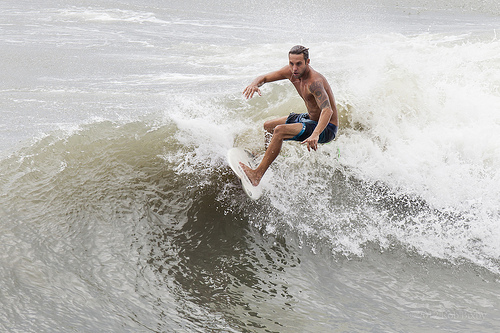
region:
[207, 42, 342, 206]
White man on surf board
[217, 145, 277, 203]
white surf board cutting wave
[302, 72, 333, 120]
tattoo on upper arm from shoulder to elbow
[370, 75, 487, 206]
froth created by rolling wave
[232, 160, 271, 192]
foot on white surf board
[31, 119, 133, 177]
top of wave about to roll over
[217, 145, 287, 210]
surf board cutting through the wave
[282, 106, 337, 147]
blue swim trunks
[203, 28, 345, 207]
man balancing on surf board on top of wave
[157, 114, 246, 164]
spray from surfboard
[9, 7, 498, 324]
Man surfing across a wave crest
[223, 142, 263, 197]
White surfboard in the water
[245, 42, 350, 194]
man with dark hair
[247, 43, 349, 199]
man in blue swimsuit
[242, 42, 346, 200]
man with tattoos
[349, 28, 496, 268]
wave crest splashing around man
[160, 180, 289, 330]
reflection cast on the grey water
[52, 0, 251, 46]
new wave forming in the distance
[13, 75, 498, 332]
waves in grey water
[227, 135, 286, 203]
bare feet on surfboard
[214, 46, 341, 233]
one man is surfing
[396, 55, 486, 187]
water is splashing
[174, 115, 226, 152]
waves are white in color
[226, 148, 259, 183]
surfing board is white in color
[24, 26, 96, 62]
water is blue in color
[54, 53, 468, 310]
daytime picture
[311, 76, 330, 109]
tattoo marks on arms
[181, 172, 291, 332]
reflection is seen in water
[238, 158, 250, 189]
letters are black in color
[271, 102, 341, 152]
trouser is black in color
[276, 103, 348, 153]
blue and black shorts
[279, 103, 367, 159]
cold, wet board shorts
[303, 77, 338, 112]
a large black arm tattoo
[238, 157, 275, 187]
a man's bare foot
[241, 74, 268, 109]
a open hand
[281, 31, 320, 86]
a man with wet hair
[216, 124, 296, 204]
a nice white surf board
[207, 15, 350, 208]
a young man surfing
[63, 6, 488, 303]
a natural ocean wave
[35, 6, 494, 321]
an ocean scene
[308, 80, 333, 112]
Large tattoo on arm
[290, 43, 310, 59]
Brown hair on man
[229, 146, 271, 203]
White surfboard in water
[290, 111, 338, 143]
Dark blue shorts with light blue trim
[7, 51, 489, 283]
Big gray wave in ocean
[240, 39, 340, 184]
Man on white surfboard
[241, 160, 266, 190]
Left foot of man on surfboard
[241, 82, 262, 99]
Open right hand of man on surfboard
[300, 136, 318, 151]
Pointing left hand of man on surfboard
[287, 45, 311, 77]
Head of man on surfboard